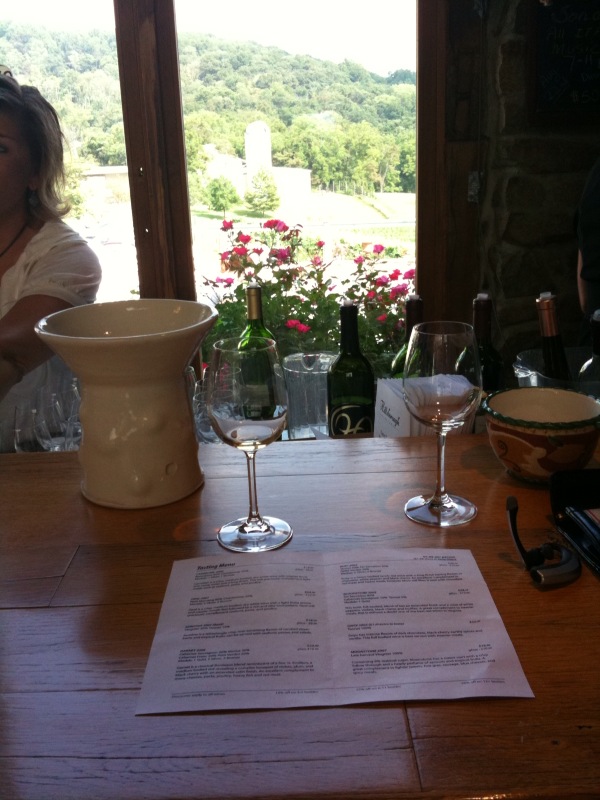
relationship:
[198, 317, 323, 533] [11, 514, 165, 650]
glass on table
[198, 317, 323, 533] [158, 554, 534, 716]
glass near menu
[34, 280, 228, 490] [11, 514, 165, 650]
bucket on table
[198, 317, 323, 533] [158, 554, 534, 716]
glass next to menu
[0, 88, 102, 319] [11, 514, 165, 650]
woman near table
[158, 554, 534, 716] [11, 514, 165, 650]
menu on table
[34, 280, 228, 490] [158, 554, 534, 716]
bucket near menu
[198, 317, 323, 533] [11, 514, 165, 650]
glass in table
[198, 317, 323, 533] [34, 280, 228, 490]
glass next to bucket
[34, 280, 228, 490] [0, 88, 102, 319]
bucket near woman